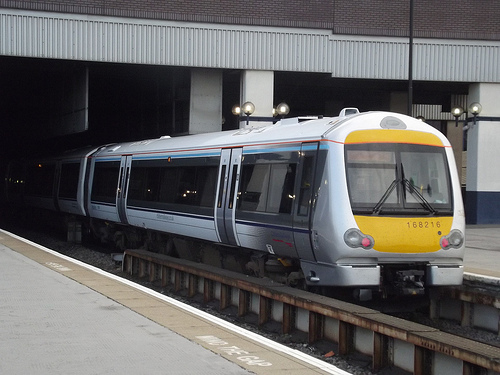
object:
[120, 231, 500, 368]
barrier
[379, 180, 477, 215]
wiper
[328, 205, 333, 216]
ground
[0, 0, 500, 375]
station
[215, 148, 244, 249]
doors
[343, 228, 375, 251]
headlight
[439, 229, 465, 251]
headlight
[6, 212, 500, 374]
track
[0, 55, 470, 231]
tunnel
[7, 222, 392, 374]
gravel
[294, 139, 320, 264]
door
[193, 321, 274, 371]
writing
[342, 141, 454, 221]
windshield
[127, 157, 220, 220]
window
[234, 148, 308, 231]
window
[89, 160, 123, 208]
window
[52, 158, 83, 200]
window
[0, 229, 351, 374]
cement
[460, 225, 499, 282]
cement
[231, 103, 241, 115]
lights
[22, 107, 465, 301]
train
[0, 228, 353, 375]
platform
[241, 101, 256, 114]
lights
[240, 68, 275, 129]
column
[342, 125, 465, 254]
front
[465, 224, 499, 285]
platform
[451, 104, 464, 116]
lighting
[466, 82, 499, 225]
pillar